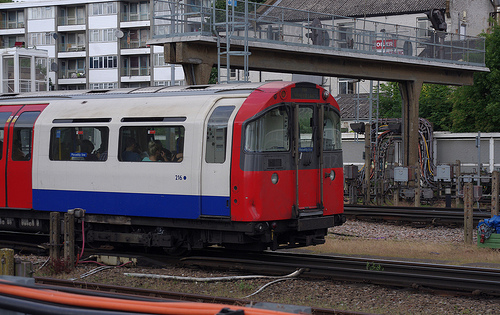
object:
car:
[0, 80, 349, 252]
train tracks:
[344, 202, 490, 228]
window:
[26, 4, 54, 21]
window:
[30, 31, 54, 46]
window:
[88, 0, 115, 17]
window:
[87, 28, 117, 42]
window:
[89, 55, 118, 70]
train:
[0, 80, 345, 260]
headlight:
[270, 172, 280, 184]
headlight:
[330, 170, 335, 180]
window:
[206, 104, 228, 163]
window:
[12, 109, 38, 160]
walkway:
[144, 4, 500, 84]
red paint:
[243, 171, 346, 219]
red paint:
[0, 159, 35, 209]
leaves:
[443, 99, 449, 104]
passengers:
[143, 139, 167, 162]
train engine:
[0, 76, 346, 256]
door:
[0, 104, 37, 208]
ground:
[0, 217, 500, 315]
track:
[285, 246, 500, 298]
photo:
[0, 3, 494, 313]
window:
[118, 123, 185, 164]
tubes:
[2, 279, 265, 313]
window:
[46, 126, 109, 160]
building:
[0, 1, 500, 187]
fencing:
[140, 3, 479, 63]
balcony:
[152, 0, 497, 86]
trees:
[447, 23, 500, 134]